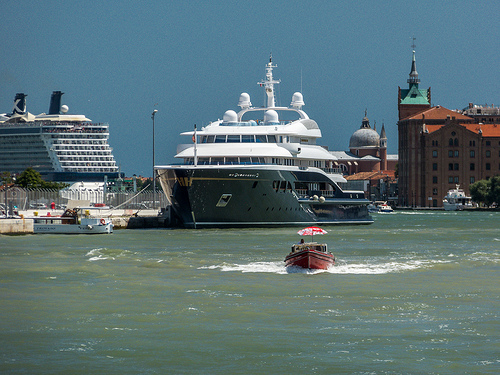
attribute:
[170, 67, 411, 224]
boat — white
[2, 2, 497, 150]
sky — blue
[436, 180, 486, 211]
boat — white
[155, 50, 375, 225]
boat — white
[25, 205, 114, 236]
boat — white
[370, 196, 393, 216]
boat — white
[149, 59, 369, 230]
ship — large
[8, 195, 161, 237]
shore — brown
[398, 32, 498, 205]
building — large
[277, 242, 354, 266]
boat — red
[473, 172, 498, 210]
trees — green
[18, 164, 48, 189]
trees — green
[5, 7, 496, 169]
sky — blue, clear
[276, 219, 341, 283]
boat — small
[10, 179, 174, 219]
metal fence — metallic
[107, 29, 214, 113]
sky — blue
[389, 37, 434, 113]
roof top — copper, tinned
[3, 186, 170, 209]
fence — chain link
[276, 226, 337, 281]
boat — red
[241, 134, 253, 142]
window — rectangular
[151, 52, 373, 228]
yacht — private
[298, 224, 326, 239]
umbrella — red